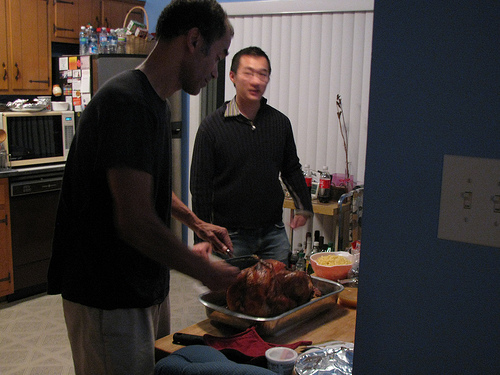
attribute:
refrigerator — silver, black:
[52, 50, 194, 270]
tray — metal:
[193, 266, 346, 336]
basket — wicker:
[106, 11, 218, 85]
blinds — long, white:
[224, 11, 375, 253]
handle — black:
[173, 329, 213, 344]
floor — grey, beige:
[1, 259, 293, 373]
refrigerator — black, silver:
[57, 45, 185, 270]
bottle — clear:
[320, 163, 332, 205]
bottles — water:
[74, 21, 133, 58]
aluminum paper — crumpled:
[292, 341, 356, 374]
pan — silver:
[199, 273, 342, 333]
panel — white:
[435, 152, 499, 250]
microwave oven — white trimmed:
[0, 109, 77, 169]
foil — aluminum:
[306, 352, 327, 368]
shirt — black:
[32, 64, 203, 311]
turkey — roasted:
[209, 251, 351, 307]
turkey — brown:
[174, 219, 345, 316]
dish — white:
[9, 105, 49, 113]